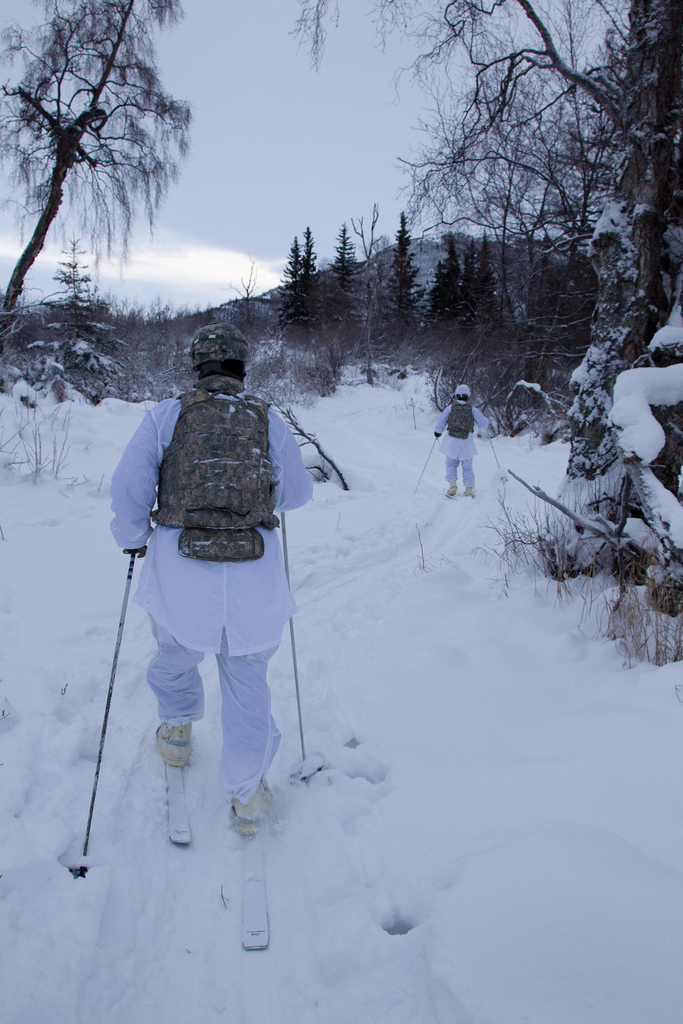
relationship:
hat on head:
[163, 314, 269, 387] [142, 345, 283, 405]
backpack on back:
[151, 376, 306, 551] [122, 366, 377, 605]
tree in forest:
[36, 233, 110, 396] [295, 237, 557, 384]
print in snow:
[344, 877, 494, 947] [447, 762, 596, 837]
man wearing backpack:
[74, 327, 364, 885] [129, 386, 291, 568]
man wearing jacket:
[109, 323, 313, 838] [107, 391, 314, 655]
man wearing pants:
[109, 323, 313, 838] [146, 616, 281, 804]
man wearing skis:
[109, 323, 313, 838] [159, 760, 273, 953]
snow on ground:
[1, 342, 682, 1022] [3, 342, 682, 1021]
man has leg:
[109, 323, 313, 838] [150, 624, 207, 766]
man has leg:
[109, 323, 313, 838] [217, 629, 284, 837]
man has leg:
[434, 384, 491, 497] [461, 460, 477, 497]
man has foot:
[109, 323, 313, 838] [155, 717, 195, 766]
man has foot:
[109, 323, 313, 838] [227, 781, 277, 838]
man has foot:
[434, 384, 491, 497] [446, 483, 460, 499]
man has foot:
[434, 384, 491, 497] [461, 487, 477, 498]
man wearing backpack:
[109, 323, 313, 838] [152, 373, 282, 564]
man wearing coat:
[109, 323, 313, 838] [107, 393, 314, 658]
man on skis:
[109, 323, 313, 838] [159, 760, 273, 953]